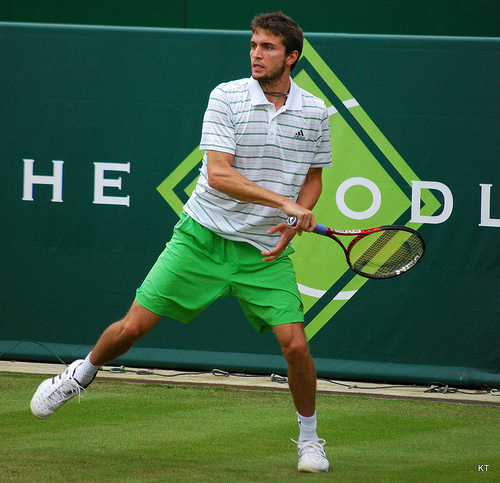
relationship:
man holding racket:
[28, 13, 331, 473] [285, 217, 426, 283]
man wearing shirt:
[28, 13, 331, 473] [184, 78, 327, 255]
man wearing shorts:
[28, 13, 331, 473] [137, 208, 307, 337]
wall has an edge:
[0, 19, 499, 399] [2, 19, 498, 46]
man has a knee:
[28, 13, 331, 473] [279, 341, 312, 358]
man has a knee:
[28, 13, 331, 473] [116, 319, 142, 347]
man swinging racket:
[28, 13, 331, 473] [285, 217, 426, 283]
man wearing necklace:
[28, 13, 331, 473] [261, 89, 287, 99]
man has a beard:
[28, 13, 331, 473] [253, 53, 289, 83]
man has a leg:
[28, 13, 331, 473] [88, 299, 164, 367]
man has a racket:
[28, 13, 331, 473] [285, 217, 426, 283]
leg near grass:
[271, 321, 319, 422] [0, 368, 499, 479]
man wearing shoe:
[28, 13, 331, 473] [26, 360, 92, 418]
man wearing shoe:
[28, 13, 331, 473] [290, 435, 330, 475]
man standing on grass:
[28, 13, 331, 473] [0, 368, 499, 479]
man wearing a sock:
[28, 13, 331, 473] [73, 353, 98, 386]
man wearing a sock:
[28, 13, 331, 473] [293, 410, 320, 443]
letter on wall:
[475, 182, 497, 232] [0, 19, 499, 399]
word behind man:
[20, 154, 498, 228] [28, 13, 331, 473]